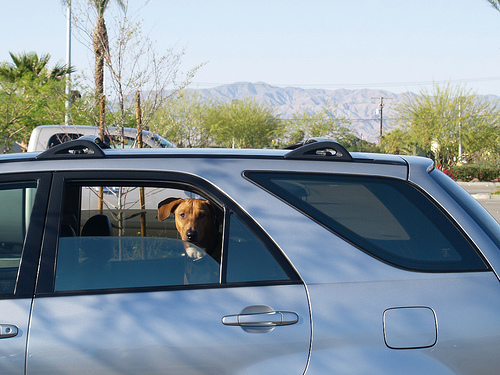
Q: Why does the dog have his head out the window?
A: To get air.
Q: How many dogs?
A: One.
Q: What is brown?
A: Dog.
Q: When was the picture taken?
A: Daytime.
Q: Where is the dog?
A: In the car.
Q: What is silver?
A: Car.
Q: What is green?
A: Trees.